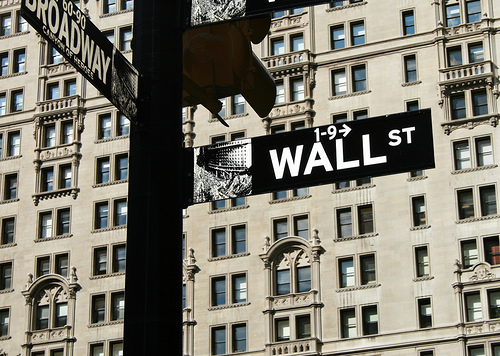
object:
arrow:
[338, 123, 352, 137]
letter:
[265, 145, 304, 180]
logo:
[192, 137, 254, 204]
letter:
[334, 137, 360, 172]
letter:
[303, 141, 335, 177]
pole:
[204, 64, 493, 254]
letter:
[361, 134, 389, 167]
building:
[7, 107, 124, 344]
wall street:
[266, 122, 419, 182]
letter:
[263, 124, 415, 179]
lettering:
[25, 0, 116, 85]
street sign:
[15, 3, 138, 129]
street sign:
[182, 104, 442, 208]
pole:
[118, 3, 202, 354]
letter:
[388, 129, 402, 147]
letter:
[402, 126, 416, 144]